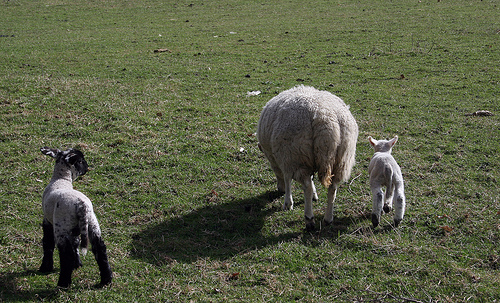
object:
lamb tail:
[313, 112, 340, 190]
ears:
[368, 136, 378, 147]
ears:
[390, 135, 398, 147]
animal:
[257, 84, 358, 231]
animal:
[368, 136, 406, 229]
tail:
[383, 165, 393, 203]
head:
[39, 146, 89, 179]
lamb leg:
[58, 244, 75, 282]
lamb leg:
[89, 237, 112, 280]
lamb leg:
[39, 224, 56, 267]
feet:
[371, 221, 380, 228]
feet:
[322, 221, 333, 227]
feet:
[306, 222, 317, 232]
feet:
[57, 284, 71, 291]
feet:
[39, 265, 53, 273]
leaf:
[157, 111, 163, 117]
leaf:
[230, 32, 237, 35]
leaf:
[463, 109, 494, 117]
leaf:
[193, 52, 200, 56]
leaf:
[153, 48, 167, 52]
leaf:
[245, 74, 251, 78]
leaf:
[400, 74, 405, 79]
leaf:
[329, 83, 334, 87]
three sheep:
[38, 84, 406, 290]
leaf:
[214, 35, 219, 38]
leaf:
[245, 74, 250, 78]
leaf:
[439, 225, 452, 231]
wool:
[44, 190, 77, 226]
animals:
[39, 146, 113, 292]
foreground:
[0, 58, 500, 303]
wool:
[259, 84, 358, 181]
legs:
[372, 187, 385, 220]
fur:
[256, 85, 359, 180]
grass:
[1, 2, 496, 299]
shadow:
[126, 190, 286, 265]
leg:
[324, 183, 338, 217]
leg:
[394, 188, 406, 221]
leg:
[304, 179, 315, 226]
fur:
[37, 222, 54, 272]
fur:
[87, 231, 112, 286]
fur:
[56, 240, 81, 289]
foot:
[389, 219, 403, 228]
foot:
[383, 205, 392, 213]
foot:
[100, 278, 112, 285]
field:
[2, 0, 484, 300]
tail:
[77, 202, 88, 256]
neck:
[52, 170, 73, 183]